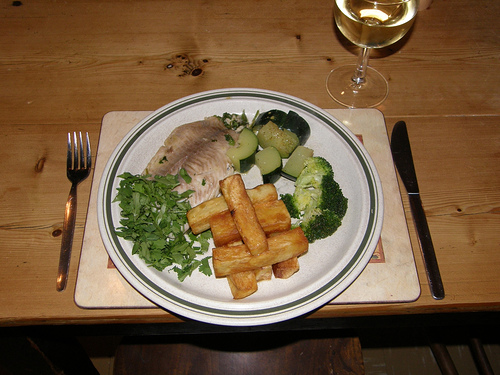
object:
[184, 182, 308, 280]
stripe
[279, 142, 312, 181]
zucchini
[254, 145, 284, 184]
zucchini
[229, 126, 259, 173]
zucchini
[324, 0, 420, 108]
glass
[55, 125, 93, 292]
fork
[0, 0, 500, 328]
table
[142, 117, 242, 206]
fish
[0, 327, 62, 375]
ground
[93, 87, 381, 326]
plate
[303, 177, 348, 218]
broccoli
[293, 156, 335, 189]
broccoli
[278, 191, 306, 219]
broccoli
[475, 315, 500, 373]
ground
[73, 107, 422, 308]
placemat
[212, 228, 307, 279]
sliced potatoes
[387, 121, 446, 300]
knife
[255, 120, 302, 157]
zucchini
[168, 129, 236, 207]
fish fillet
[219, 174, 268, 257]
fries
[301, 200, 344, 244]
broccoli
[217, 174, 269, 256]
potatoes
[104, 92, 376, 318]
rim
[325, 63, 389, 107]
bottom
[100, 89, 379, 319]
ring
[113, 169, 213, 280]
parsley